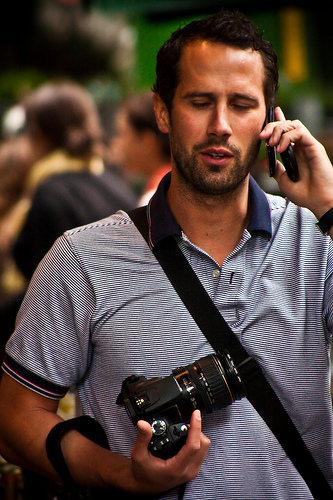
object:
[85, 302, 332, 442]
chest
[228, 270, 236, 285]
hole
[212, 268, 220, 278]
button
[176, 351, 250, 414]
lens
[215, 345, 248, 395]
tip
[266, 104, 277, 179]
cellphone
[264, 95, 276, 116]
ear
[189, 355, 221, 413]
dial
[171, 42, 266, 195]
face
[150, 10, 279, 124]
hair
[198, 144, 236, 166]
lips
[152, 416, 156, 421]
button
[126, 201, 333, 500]
strap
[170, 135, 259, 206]
beard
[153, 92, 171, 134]
ear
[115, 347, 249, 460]
camera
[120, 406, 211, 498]
hand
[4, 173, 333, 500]
shirt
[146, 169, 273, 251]
collar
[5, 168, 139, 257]
shirt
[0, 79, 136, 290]
person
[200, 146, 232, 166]
mouth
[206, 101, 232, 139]
nose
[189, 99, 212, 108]
eye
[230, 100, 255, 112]
eye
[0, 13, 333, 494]
cameraman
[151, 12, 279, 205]
head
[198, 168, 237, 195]
chin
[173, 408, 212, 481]
fingers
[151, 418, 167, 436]
camera dial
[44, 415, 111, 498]
camera strap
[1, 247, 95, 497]
arm